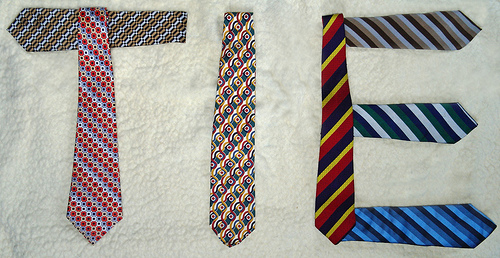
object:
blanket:
[0, 0, 500, 258]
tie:
[339, 202, 499, 251]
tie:
[344, 10, 484, 52]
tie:
[313, 13, 357, 246]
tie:
[64, 5, 127, 246]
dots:
[81, 92, 87, 98]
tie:
[352, 101, 479, 145]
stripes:
[399, 205, 456, 247]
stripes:
[386, 103, 428, 143]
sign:
[6, 6, 189, 246]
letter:
[312, 9, 498, 249]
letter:
[208, 11, 258, 248]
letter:
[5, 6, 189, 247]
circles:
[92, 118, 97, 123]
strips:
[367, 16, 409, 49]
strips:
[321, 37, 346, 71]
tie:
[207, 11, 258, 249]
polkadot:
[88, 50, 94, 56]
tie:
[6, 7, 189, 53]